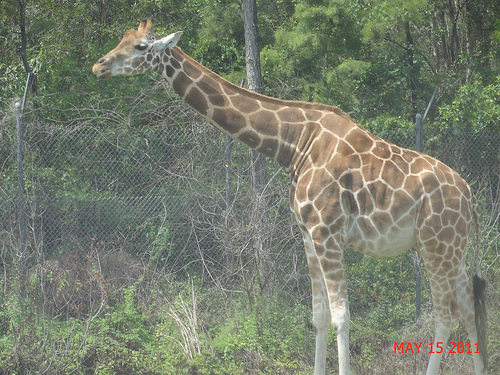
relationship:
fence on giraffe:
[23, 129, 181, 299] [96, 26, 488, 370]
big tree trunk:
[157, 34, 327, 173] [242, 3, 266, 93]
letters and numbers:
[391, 341, 423, 355] [431, 341, 481, 355]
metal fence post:
[14, 104, 127, 233] [14, 102, 24, 250]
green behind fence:
[52, 31, 82, 81] [23, 129, 181, 299]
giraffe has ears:
[96, 26, 488, 370] [151, 28, 187, 58]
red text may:
[394, 336, 478, 358] [391, 335, 425, 362]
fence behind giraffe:
[23, 129, 181, 299] [96, 26, 488, 370]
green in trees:
[52, 31, 82, 81] [300, 18, 457, 90]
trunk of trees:
[242, 3, 266, 93] [300, 18, 457, 90]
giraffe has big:
[96, 26, 488, 370] [157, 34, 327, 173]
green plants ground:
[52, 31, 82, 81] [18, 351, 326, 374]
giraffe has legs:
[96, 26, 488, 370] [302, 222, 482, 371]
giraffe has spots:
[96, 26, 488, 370] [319, 137, 369, 197]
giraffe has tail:
[96, 26, 488, 370] [463, 191, 493, 361]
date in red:
[394, 336, 478, 358] [393, 344, 477, 355]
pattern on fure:
[312, 152, 393, 230] [181, 91, 232, 117]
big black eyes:
[102, 34, 402, 215] [134, 38, 148, 53]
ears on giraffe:
[151, 28, 187, 58] [96, 26, 488, 370]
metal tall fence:
[14, 104, 127, 233] [23, 129, 181, 299]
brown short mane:
[175, 75, 189, 96] [173, 45, 346, 118]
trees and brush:
[300, 18, 457, 90] [190, 185, 291, 299]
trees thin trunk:
[300, 18, 457, 90] [242, 3, 266, 93]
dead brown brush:
[47, 252, 154, 304] [190, 185, 291, 299]